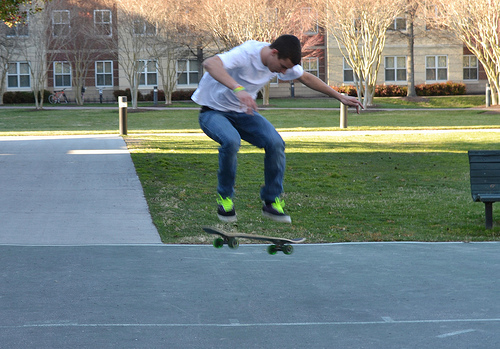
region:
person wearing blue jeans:
[181, 19, 366, 229]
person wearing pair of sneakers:
[208, 190, 295, 231]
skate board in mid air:
[200, 221, 308, 263]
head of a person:
[252, 28, 311, 83]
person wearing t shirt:
[196, 32, 316, 127]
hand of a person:
[207, 75, 264, 120]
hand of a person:
[340, 84, 367, 119]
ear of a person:
[264, 38, 283, 57]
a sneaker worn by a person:
[260, 191, 302, 231]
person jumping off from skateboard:
[152, 22, 375, 295]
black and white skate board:
[206, 225, 306, 243]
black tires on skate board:
[214, 236, 237, 249]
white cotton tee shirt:
[192, 40, 302, 113]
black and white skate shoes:
[216, 193, 292, 225]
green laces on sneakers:
[216, 195, 234, 213]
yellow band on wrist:
[234, 83, 243, 93]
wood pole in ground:
[118, 95, 128, 136]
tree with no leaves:
[324, 3, 398, 113]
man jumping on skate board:
[188, 35, 363, 254]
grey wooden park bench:
[464, 150, 499, 224]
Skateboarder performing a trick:
[186, 29, 366, 258]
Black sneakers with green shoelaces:
[209, 188, 295, 229]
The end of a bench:
[462, 140, 498, 228]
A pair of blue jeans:
[196, 105, 290, 205]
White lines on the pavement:
[17, 307, 498, 342]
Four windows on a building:
[46, 7, 118, 95]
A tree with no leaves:
[11, 14, 71, 111]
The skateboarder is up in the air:
[184, 29, 368, 264]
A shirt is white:
[187, 37, 305, 116]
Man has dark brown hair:
[267, 30, 305, 78]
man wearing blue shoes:
[214, 192, 240, 221]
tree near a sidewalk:
[329, 28, 390, 115]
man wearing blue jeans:
[194, 101, 293, 197]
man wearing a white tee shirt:
[190, 37, 306, 118]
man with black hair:
[269, 33, 302, 65]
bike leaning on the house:
[48, 80, 70, 106]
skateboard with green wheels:
[208, 235, 242, 248]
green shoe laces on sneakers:
[216, 188, 233, 213]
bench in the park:
[460, 142, 499, 214]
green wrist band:
[231, 78, 248, 100]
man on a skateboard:
[183, 183, 361, 273]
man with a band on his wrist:
[227, 82, 249, 95]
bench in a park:
[459, 140, 499, 242]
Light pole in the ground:
[113, 85, 136, 138]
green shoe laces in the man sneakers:
[209, 194, 237, 216]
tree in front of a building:
[66, 14, 87, 111]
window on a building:
[384, 51, 412, 81]